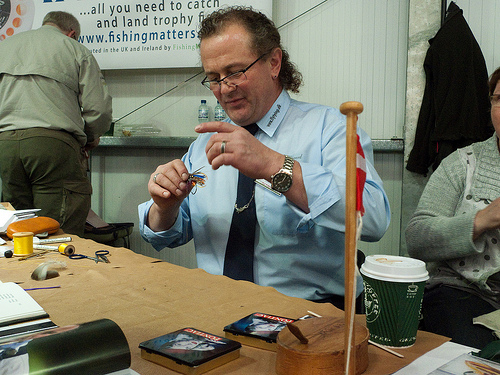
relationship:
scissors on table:
[65, 249, 117, 273] [0, 204, 500, 375]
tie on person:
[220, 124, 260, 281] [136, 6, 391, 314]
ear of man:
[258, 40, 298, 103] [130, 5, 395, 313]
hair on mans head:
[231, 10, 299, 73] [166, 14, 297, 139]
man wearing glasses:
[130, 5, 395, 313] [198, 54, 280, 96]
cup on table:
[364, 246, 438, 341] [4, 217, 444, 373]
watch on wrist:
[269, 155, 297, 194] [264, 149, 301, 199]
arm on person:
[123, 119, 393, 242] [418, 152, 482, 244]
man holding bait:
[124, 14, 392, 295] [174, 160, 214, 187]